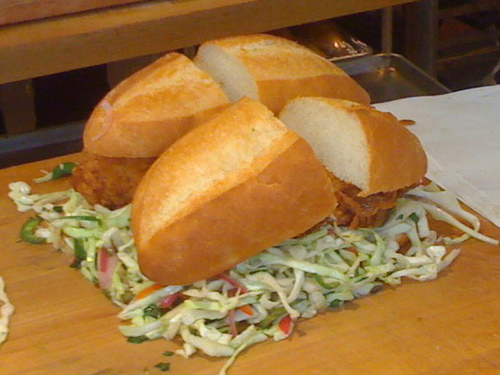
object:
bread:
[127, 95, 338, 291]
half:
[278, 94, 429, 200]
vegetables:
[181, 275, 458, 313]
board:
[0, 165, 82, 374]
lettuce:
[64, 210, 130, 325]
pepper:
[19, 209, 52, 244]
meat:
[63, 145, 131, 214]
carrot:
[226, 299, 261, 342]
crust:
[80, 52, 232, 162]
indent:
[260, 73, 376, 101]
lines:
[314, 313, 495, 372]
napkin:
[389, 84, 498, 224]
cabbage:
[298, 236, 408, 301]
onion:
[221, 272, 273, 298]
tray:
[322, 50, 450, 105]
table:
[0, 289, 500, 375]